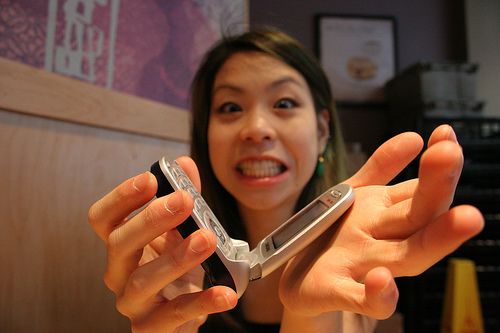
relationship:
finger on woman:
[384, 105, 484, 276] [379, 131, 497, 259]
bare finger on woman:
[118, 219, 218, 316] [76, 20, 484, 329]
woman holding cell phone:
[76, 20, 484, 329] [137, 141, 360, 303]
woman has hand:
[76, 20, 484, 329] [352, 125, 479, 294]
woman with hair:
[76, 20, 484, 329] [188, 5, 340, 242]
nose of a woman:
[233, 110, 276, 144] [76, 20, 484, 329]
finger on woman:
[337, 122, 487, 319] [131, 37, 427, 330]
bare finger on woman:
[87, 156, 239, 331] [76, 20, 484, 329]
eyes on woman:
[206, 91, 309, 120] [76, 20, 484, 329]